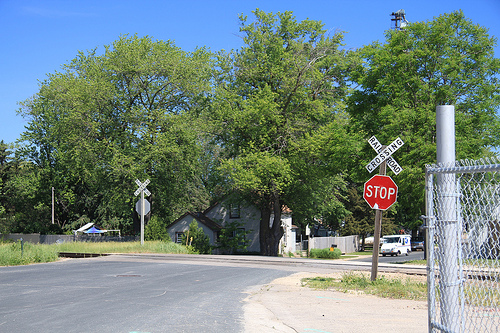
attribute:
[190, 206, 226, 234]
roof — slanted, brown, gray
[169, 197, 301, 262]
house — brown, white, small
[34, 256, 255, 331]
street — gray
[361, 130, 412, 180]
sign — white, black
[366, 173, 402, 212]
stop sign — red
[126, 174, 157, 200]
crossing sign — white, black, x shaped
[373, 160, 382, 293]
pole — metal, gray, wooden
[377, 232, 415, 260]
van — white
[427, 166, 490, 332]
fence — metal, chained, gray, silver, linked, chain, grey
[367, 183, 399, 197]
letters — white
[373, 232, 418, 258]
truck — white, small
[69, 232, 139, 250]
fence — white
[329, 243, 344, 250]
mailbox — black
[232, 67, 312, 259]
tree — large, green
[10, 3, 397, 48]
sky — clear, blue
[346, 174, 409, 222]
traffic sign — red, white